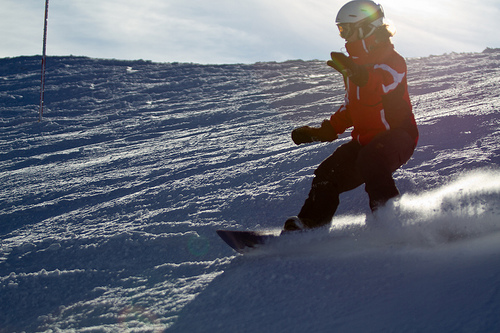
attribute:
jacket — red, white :
[313, 42, 413, 138]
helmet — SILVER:
[335, 1, 385, 26]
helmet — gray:
[334, 1, 389, 41]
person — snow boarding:
[274, 0, 419, 231]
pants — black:
[297, 129, 421, 216]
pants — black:
[284, 146, 396, 231]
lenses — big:
[320, 15, 352, 41]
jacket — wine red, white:
[328, 38, 410, 136]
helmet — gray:
[333, 0, 383, 35]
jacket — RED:
[306, 24, 426, 168]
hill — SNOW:
[12, 68, 263, 295]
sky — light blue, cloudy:
[18, 6, 486, 56]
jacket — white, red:
[322, 42, 415, 140]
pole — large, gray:
[8, 14, 140, 111]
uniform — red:
[293, 23, 421, 232]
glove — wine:
[289, 121, 321, 145]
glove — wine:
[325, 50, 369, 85]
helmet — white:
[330, 0, 390, 41]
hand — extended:
[326, 57, 367, 87]